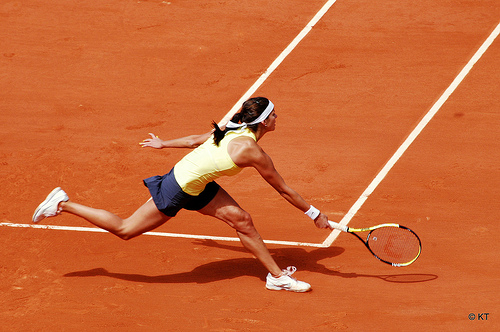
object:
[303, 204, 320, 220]
sweat band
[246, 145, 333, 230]
arm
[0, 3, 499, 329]
court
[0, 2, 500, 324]
tennis court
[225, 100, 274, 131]
headband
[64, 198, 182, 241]
right leg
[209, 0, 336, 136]
line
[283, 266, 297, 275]
laces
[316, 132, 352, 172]
ground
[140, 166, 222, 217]
skirt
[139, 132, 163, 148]
hand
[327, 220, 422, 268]
racket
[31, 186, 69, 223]
shoe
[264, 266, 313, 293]
shoe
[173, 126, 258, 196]
shirt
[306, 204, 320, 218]
wrist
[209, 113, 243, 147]
tail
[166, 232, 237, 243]
line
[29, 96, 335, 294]
player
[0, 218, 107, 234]
line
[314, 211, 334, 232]
hand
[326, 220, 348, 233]
grip